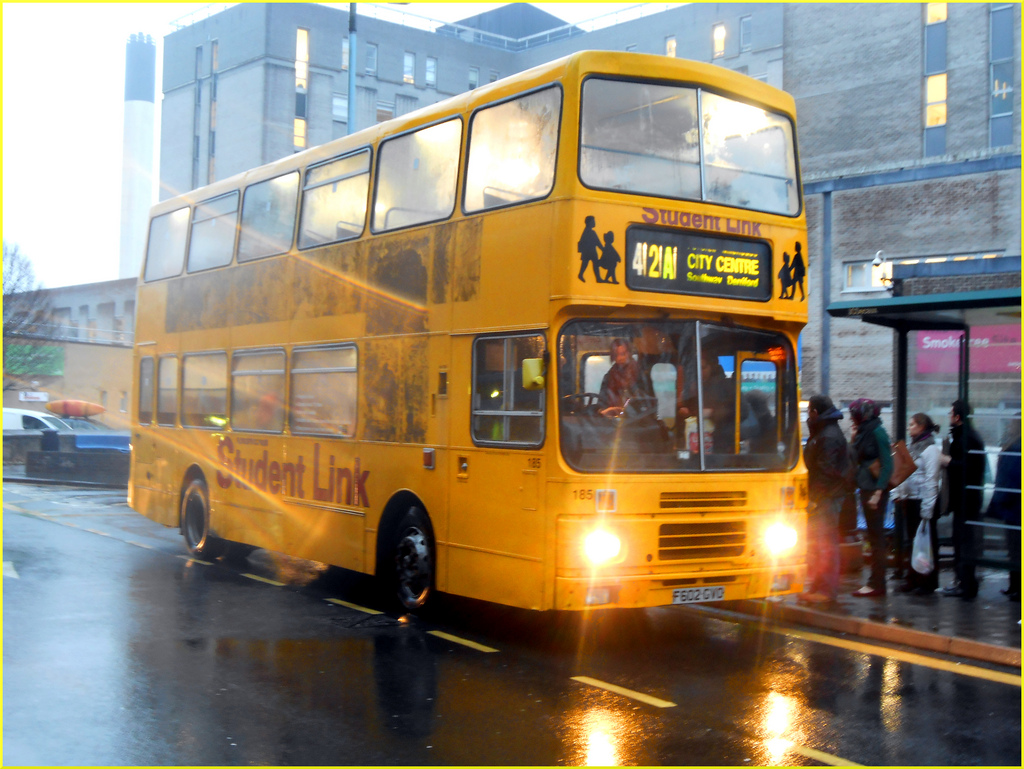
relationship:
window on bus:
[337, 109, 485, 254] [91, 46, 824, 679]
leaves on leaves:
[16, 288, 36, 347] [3, 241, 67, 392]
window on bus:
[467, 333, 537, 442] [122, 48, 833, 617]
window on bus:
[286, 340, 356, 444] [122, 48, 833, 617]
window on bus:
[224, 350, 285, 435] [122, 48, 833, 617]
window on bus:
[174, 344, 229, 433] [122, 48, 833, 617]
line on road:
[738, 718, 849, 764] [3, 474, 1012, 762]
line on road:
[556, 666, 680, 721] [3, 474, 1012, 762]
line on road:
[424, 612, 505, 654] [3, 474, 1012, 762]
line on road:
[314, 573, 395, 630] [3, 474, 1012, 762]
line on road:
[232, 560, 302, 604] [3, 474, 1012, 762]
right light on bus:
[569, 519, 632, 571] [122, 48, 833, 617]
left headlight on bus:
[746, 508, 811, 571] [122, 48, 833, 617]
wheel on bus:
[379, 482, 436, 614] [122, 48, 833, 617]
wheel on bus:
[170, 469, 212, 552] [122, 48, 833, 617]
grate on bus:
[647, 471, 751, 573] [122, 48, 833, 617]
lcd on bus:
[625, 223, 772, 302] [122, 48, 833, 617]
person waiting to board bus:
[850, 398, 896, 598] [122, 48, 833, 617]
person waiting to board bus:
[837, 389, 917, 619] [122, 48, 833, 617]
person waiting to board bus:
[893, 407, 954, 574] [122, 48, 833, 617]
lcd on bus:
[617, 229, 778, 299] [122, 48, 833, 617]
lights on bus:
[558, 500, 801, 576] [122, 48, 833, 617]